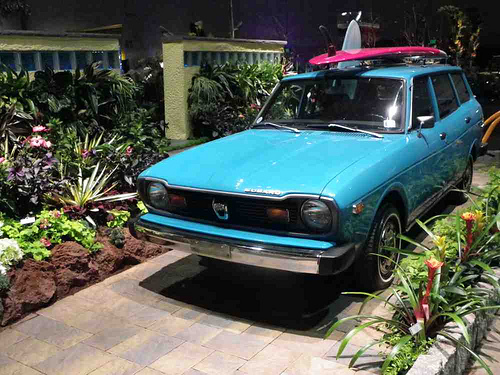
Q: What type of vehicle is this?
A: Car.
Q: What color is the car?
A: Teal.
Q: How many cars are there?
A: One.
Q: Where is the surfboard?
A: Top of the car.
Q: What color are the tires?
A: Black.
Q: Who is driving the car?
A: No one.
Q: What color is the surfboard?
A: Pink.